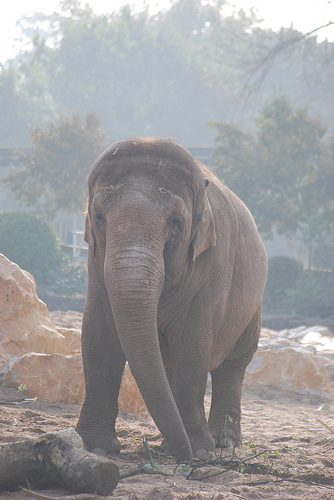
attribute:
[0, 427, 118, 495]
log — grey, dead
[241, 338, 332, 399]
rock — tan, heavy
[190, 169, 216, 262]
ear — big, gray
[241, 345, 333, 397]
rock — big, heavy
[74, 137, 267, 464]
elephant — large, happy, big, lumber, front left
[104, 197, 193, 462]
trunk — long, useful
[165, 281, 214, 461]
leg — front right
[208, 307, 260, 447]
leg — back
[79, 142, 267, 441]
elephant — dark gray, very big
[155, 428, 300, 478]
branches — thin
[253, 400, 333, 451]
dirt — tan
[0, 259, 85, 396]
rocks — orange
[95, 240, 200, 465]
trunk — long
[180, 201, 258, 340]
skin — wrinkley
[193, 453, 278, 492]
mud — light brown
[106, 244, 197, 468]
trunk — long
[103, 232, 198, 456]
trunk — long